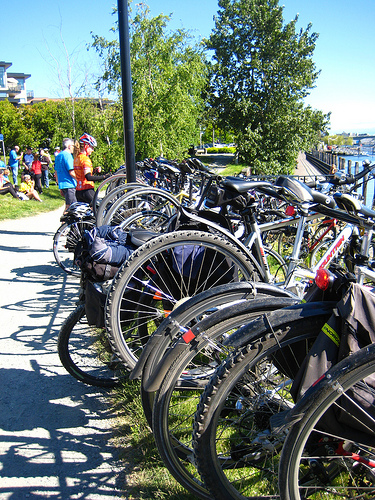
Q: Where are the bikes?
A: In the grass.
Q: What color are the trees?
A: Green.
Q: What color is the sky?
A: Blue.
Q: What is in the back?
A: Trees.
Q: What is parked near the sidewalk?
A: Bicycles.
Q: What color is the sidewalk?
A: Grey.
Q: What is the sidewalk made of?
A: Cement.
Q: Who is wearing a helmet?
A: Man in the orange shirt.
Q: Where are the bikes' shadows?
A: On the sidewalk.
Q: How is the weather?
A: Bright and clear.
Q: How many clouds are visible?
A: None.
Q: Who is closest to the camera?
A: The man with a helmet.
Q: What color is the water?
A: Blue.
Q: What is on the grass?
A: Bikes.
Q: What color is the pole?
A: Black.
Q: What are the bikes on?
A: Bike rack.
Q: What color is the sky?
A: Blue.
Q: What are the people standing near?
A: A beach.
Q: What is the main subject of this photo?
A: The bikes.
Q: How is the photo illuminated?
A: Sunlight.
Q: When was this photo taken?
A: During the day.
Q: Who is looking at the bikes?
A: The man in the helmet.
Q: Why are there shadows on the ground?
A: The bikes.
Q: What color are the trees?
A: Green.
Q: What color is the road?
A: Gray.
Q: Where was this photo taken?
A: Next to bikes.